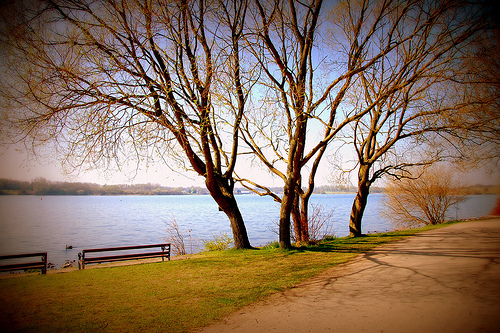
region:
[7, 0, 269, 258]
a tree with leaves on it.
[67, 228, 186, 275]
a bench near a river.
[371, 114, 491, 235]
a leafless tree.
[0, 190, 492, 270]
a large body of water.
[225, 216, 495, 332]
a dirt road near water.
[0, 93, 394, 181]
clouds in a blue sky.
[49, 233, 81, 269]
a group of animals.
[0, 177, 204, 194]
a set of small foot hills.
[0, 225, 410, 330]
a field of green grass.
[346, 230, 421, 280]
shadow cast by a tree.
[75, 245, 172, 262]
wood bench on side of lake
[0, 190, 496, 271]
large blue and clear lake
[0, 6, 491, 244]
large leafless trees on side of lake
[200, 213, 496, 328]
light brown pathway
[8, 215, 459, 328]
green grassy area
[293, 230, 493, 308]
shadow of tree casted on ground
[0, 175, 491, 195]
area of land behind the lake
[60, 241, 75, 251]
duck floating in the water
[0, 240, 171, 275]
two benches on side of lake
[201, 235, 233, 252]
small green shrub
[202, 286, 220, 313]
edge of a lawn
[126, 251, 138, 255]
part of a bench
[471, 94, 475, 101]
part of a branch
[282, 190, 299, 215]
stem of a tree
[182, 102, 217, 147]
leaves of a tree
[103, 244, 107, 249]
edge of a bench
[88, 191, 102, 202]
edge of a sea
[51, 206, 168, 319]
Bench on the side of the shore.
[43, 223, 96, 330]
Animal in the water.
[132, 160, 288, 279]
Plant by the water.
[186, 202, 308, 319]
Grass on the ground.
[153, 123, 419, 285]
Trunks of the trees.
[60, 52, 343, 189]
Bare tree branches.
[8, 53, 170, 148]
Leaves and buds on the branches.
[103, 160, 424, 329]
Water in the background.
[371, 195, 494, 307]
Road by the trees.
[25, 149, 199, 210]
Trees in the distance.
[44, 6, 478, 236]
four trees with no leaves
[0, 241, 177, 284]
benches on the grass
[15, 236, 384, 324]
green and yellow grass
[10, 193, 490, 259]
light blue lake with ripples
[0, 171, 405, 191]
line of trees on the other side of a lake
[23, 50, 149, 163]
light brown bare branches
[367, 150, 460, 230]
top of a small tree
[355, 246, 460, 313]
shadow cast by a tree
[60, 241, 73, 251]
bird floating on the water